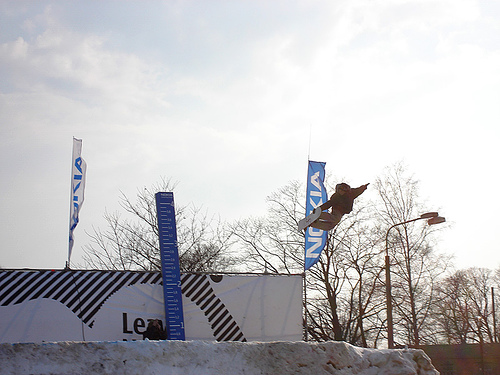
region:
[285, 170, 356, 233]
the man is snowboarding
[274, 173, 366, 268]
the man is snowboarding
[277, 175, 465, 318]
the man is snowboarding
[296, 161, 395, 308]
the man is snowboarding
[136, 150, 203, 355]
a tall blue ruler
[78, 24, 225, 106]
this is the sky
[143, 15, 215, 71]
the sky is blue in color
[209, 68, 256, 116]
this is the cloud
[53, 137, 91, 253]
this is a flag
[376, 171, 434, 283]
this is the tree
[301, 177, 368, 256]
this is a man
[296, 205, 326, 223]
this is a skate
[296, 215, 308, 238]
the skate board is white in color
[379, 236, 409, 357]
this is a pole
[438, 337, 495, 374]
this is a wall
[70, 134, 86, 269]
white banner with blue font letters in the wind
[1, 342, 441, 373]
pile of dirty brown snow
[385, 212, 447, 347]
pole type street lamp unilluminated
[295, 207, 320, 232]
white snowboard with brown logo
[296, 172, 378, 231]
snowboarder doing a radical trick in midair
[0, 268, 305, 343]
white billboard with a zebra stripe pattern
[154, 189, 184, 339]
blue column with white lines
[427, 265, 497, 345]
group of brown trees with no leaves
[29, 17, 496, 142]
baby blue sky with wispy white clouds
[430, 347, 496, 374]
brownish red wooden barrier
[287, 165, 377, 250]
the man is in the air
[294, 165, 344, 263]
the brand is nokia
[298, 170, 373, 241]
the guy is perfoming a stunt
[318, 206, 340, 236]
the pants are brown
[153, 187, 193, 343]
the board is blue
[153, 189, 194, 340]
the board has marking on it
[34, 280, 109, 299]
the strips are black and white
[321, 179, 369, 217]
the guy has a marvin on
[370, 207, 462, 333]
the light post is curved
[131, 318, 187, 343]
the guy is spectating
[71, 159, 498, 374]
the tall and bare trees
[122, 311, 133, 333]
the black letter "L" on the banner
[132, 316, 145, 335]
the black letter "e" on the banner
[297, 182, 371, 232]
the snowboarder in mid air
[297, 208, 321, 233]
the snowboard in mid air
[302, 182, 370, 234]
the person in mid air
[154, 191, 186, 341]
the large blue ruler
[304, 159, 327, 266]
the blue NOKIA fabric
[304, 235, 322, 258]
the white "N" on the blue fabric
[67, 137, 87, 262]
the white fabric with NOKIA on it